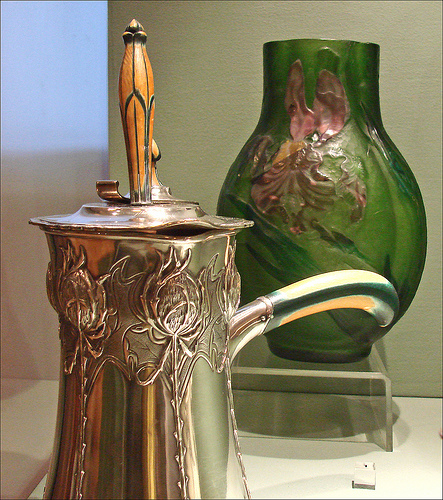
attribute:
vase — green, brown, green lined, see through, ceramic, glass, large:
[217, 36, 431, 366]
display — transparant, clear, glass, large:
[217, 337, 401, 451]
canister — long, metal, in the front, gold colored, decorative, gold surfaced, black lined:
[29, 15, 400, 499]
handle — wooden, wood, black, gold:
[114, 17, 166, 207]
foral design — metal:
[120, 245, 219, 499]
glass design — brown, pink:
[255, 48, 371, 240]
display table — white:
[2, 369, 442, 499]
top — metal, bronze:
[34, 201, 258, 242]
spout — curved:
[230, 256, 400, 364]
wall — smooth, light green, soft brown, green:
[105, 2, 440, 408]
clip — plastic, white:
[349, 470, 375, 493]